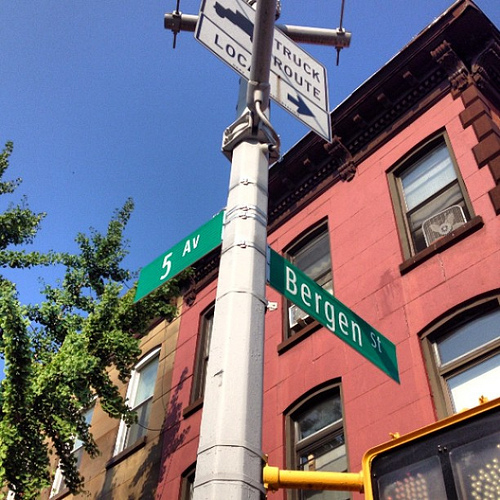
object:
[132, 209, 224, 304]
street sign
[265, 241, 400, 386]
street sign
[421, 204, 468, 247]
fan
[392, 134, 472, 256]
window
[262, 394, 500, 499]
street light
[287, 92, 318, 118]
arrow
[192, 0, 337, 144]
sign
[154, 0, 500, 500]
building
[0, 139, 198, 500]
tree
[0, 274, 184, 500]
building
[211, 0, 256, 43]
truck graphic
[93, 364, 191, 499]
shadow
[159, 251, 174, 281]
5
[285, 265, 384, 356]
bergen st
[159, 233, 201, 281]
5 av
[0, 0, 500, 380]
sky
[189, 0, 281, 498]
pole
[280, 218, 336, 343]
window